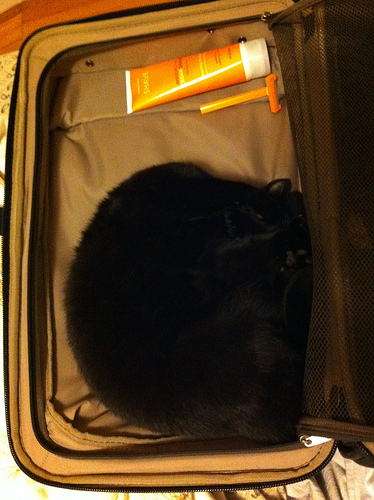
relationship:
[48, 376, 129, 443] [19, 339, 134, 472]
stitching around corner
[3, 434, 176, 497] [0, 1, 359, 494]
fabric under suitcase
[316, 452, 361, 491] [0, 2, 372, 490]
brown fabric under case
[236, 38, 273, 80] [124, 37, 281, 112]
whitecap on items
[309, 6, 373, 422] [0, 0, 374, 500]
fabric on case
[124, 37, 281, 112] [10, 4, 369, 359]
items in luggage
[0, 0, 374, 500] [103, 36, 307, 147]
case with items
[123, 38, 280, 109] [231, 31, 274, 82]
tube with cap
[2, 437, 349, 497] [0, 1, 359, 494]
zipper on side of suitcase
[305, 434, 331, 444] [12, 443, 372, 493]
tab on zipper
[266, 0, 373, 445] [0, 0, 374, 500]
fabric inside case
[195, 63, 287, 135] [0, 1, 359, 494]
razor in suitcase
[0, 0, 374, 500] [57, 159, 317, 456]
case containing cat